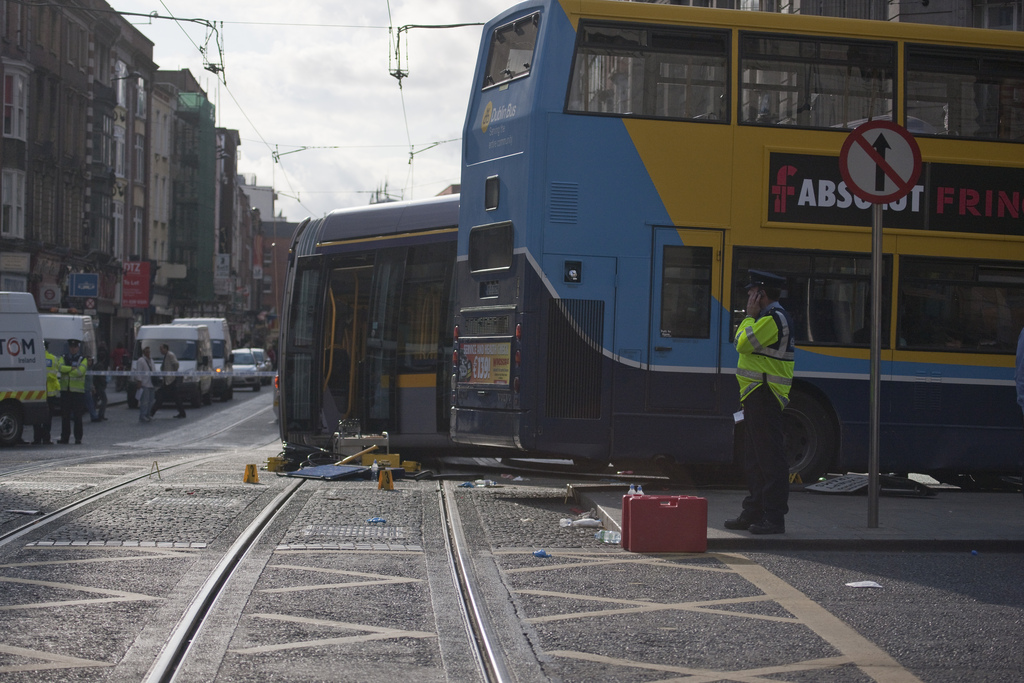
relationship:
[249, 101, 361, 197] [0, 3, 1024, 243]
clouds in sky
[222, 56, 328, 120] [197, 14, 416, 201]
clouds in sky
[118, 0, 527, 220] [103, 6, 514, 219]
white clouds in sky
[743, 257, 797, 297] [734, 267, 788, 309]
hat on head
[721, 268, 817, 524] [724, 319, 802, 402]
policeman in yellow coat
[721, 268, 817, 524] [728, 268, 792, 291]
policeman in black hat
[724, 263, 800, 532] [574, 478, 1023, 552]
policeman on sidewalk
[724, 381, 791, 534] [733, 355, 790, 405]
man`s legs below torso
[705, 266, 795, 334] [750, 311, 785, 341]
head above shoulders